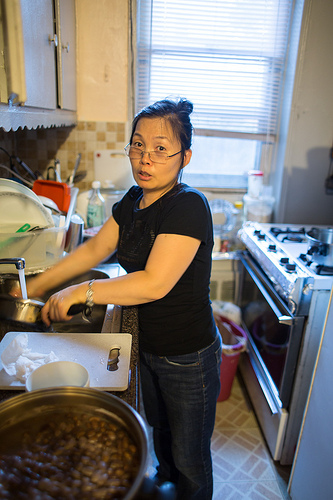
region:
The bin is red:
[211, 311, 244, 403]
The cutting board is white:
[3, 331, 133, 390]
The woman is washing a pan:
[3, 98, 226, 493]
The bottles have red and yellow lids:
[230, 170, 263, 225]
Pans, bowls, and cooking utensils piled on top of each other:
[1, 159, 72, 265]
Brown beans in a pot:
[4, 389, 150, 496]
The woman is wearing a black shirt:
[116, 98, 215, 356]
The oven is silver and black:
[234, 218, 328, 462]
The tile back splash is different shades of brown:
[18, 121, 124, 191]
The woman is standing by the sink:
[4, 97, 216, 488]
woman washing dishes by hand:
[3, 51, 214, 354]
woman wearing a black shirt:
[93, 168, 223, 358]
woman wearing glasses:
[122, 129, 182, 169]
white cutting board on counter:
[0, 309, 137, 396]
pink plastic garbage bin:
[211, 298, 247, 407]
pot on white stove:
[295, 213, 331, 317]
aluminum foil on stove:
[234, 217, 305, 315]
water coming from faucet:
[0, 251, 36, 303]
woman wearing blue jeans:
[139, 342, 226, 498]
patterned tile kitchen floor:
[215, 409, 272, 498]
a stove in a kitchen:
[234, 221, 331, 465]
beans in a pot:
[2, 389, 150, 498]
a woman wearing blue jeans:
[138, 326, 222, 497]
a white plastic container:
[24, 359, 91, 390]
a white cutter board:
[2, 328, 131, 394]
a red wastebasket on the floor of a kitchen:
[213, 311, 246, 401]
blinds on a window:
[135, 1, 301, 138]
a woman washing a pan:
[1, 276, 86, 327]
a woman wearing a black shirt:
[111, 182, 216, 350]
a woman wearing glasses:
[125, 139, 183, 164]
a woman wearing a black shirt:
[76, 161, 260, 358]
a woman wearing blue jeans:
[127, 309, 246, 486]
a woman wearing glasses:
[94, 131, 201, 184]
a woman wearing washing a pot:
[9, 247, 129, 323]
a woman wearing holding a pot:
[15, 215, 143, 343]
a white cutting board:
[15, 307, 158, 394]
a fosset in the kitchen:
[8, 229, 57, 315]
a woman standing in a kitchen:
[74, 120, 254, 350]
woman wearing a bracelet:
[72, 273, 117, 325]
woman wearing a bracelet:
[82, 276, 101, 322]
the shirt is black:
[96, 189, 243, 391]